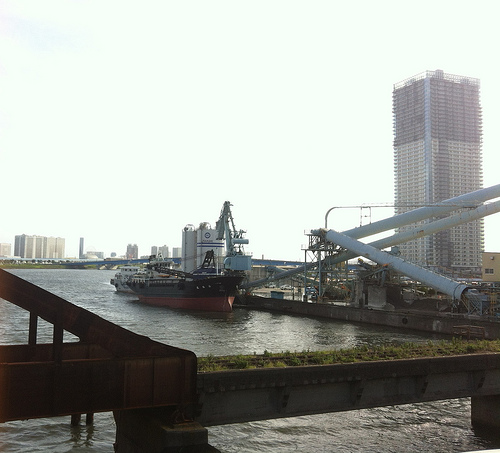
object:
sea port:
[65, 199, 460, 320]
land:
[348, 349, 389, 360]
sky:
[5, 4, 377, 204]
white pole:
[323, 229, 490, 312]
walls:
[187, 239, 195, 255]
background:
[13, 224, 325, 288]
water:
[184, 323, 232, 349]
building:
[79, 237, 85, 259]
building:
[0, 243, 11, 257]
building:
[151, 245, 157, 255]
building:
[182, 221, 225, 273]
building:
[392, 68, 486, 277]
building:
[14, 233, 66, 259]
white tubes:
[338, 183, 500, 240]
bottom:
[138, 297, 236, 314]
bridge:
[0, 267, 500, 453]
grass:
[196, 336, 498, 375]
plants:
[200, 339, 495, 374]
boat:
[125, 249, 244, 315]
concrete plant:
[147, 202, 333, 291]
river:
[0, 268, 500, 453]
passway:
[189, 340, 499, 376]